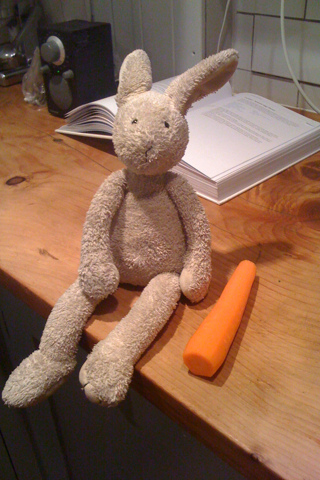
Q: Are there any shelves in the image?
A: No, there are no shelves.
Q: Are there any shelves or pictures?
A: No, there are no shelves or pictures.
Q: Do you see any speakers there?
A: Yes, there is a speaker.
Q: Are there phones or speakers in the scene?
A: Yes, there is a speaker.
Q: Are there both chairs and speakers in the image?
A: No, there is a speaker but no chairs.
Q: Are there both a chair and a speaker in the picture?
A: No, there is a speaker but no chairs.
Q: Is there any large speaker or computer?
A: Yes, there is a large speaker.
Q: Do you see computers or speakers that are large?
A: Yes, the speaker is large.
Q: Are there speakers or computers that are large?
A: Yes, the speaker is large.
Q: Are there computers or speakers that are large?
A: Yes, the speaker is large.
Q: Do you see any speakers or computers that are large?
A: Yes, the speaker is large.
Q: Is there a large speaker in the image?
A: Yes, there is a large speaker.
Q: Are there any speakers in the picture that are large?
A: Yes, there is a speaker that is large.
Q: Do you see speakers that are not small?
A: Yes, there is a large speaker.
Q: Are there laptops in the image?
A: No, there are no laptops.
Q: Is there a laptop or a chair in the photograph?
A: No, there are no laptops or chairs.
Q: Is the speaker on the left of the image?
A: Yes, the speaker is on the left of the image.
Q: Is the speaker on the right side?
A: No, the speaker is on the left of the image.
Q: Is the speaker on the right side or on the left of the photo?
A: The speaker is on the left of the image.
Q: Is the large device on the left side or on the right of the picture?
A: The speaker is on the left of the image.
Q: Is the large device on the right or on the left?
A: The speaker is on the left of the image.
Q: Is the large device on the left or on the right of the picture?
A: The speaker is on the left of the image.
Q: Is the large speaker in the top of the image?
A: Yes, the speaker is in the top of the image.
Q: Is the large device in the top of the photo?
A: Yes, the speaker is in the top of the image.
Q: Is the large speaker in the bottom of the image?
A: No, the speaker is in the top of the image.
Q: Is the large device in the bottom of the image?
A: No, the speaker is in the top of the image.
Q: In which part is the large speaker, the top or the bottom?
A: The speaker is in the top of the image.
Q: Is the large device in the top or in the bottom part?
A: The speaker is in the top of the image.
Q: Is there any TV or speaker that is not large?
A: No, there is a speaker but it is large.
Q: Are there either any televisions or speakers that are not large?
A: No, there is a speaker but it is large.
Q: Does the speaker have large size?
A: Yes, the speaker is large.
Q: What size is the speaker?
A: The speaker is large.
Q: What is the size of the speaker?
A: The speaker is large.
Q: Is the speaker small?
A: No, the speaker is large.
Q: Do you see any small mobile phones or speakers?
A: No, there is a speaker but it is large.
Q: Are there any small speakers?
A: No, there is a speaker but it is large.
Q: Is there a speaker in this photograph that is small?
A: No, there is a speaker but it is large.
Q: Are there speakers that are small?
A: No, there is a speaker but it is large.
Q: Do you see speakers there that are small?
A: No, there is a speaker but it is large.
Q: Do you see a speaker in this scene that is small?
A: No, there is a speaker but it is large.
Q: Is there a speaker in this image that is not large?
A: No, there is a speaker but it is large.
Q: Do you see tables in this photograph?
A: Yes, there is a table.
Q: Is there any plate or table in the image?
A: Yes, there is a table.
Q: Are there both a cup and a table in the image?
A: No, there is a table but no cups.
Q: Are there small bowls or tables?
A: Yes, there is a small table.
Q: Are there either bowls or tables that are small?
A: Yes, the table is small.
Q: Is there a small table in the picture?
A: Yes, there is a small table.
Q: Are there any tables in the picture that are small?
A: Yes, there is a table that is small.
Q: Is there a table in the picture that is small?
A: Yes, there is a table that is small.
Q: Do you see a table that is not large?
A: Yes, there is a small table.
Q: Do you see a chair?
A: No, there are no chairs.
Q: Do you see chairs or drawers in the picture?
A: No, there are no chairs or drawers.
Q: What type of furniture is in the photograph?
A: The furniture is a table.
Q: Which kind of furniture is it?
A: The piece of furniture is a table.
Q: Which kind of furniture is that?
A: This is a table.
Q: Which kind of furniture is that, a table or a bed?
A: This is a table.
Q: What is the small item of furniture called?
A: The piece of furniture is a table.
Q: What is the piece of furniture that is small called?
A: The piece of furniture is a table.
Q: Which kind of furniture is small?
A: The furniture is a table.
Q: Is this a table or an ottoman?
A: This is a table.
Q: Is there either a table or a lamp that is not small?
A: No, there is a table but it is small.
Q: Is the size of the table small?
A: Yes, the table is small.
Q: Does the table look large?
A: No, the table is small.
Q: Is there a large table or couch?
A: No, there is a table but it is small.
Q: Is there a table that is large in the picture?
A: No, there is a table but it is small.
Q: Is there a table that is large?
A: No, there is a table but it is small.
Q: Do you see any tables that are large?
A: No, there is a table but it is small.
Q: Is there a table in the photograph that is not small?
A: No, there is a table but it is small.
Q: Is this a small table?
A: Yes, this is a small table.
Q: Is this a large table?
A: No, this is a small table.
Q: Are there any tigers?
A: No, there are no tigers.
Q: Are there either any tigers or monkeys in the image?
A: No, there are no tigers or monkeys.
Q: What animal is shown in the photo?
A: The animal is a bunny.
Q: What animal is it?
A: The animal is a bunny.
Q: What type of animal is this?
A: This is a bunny.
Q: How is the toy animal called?
A: The animal is a bunny.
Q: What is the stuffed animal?
A: The animal is a bunny.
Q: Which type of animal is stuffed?
A: The animal is a bunny.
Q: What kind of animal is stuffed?
A: The animal is a bunny.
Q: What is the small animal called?
A: The animal is a bunny.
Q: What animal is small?
A: The animal is a bunny.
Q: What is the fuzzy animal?
A: The animal is a bunny.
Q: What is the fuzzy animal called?
A: The animal is a bunny.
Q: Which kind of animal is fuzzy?
A: The animal is a bunny.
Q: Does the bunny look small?
A: Yes, the bunny is small.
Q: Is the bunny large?
A: No, the bunny is small.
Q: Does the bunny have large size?
A: No, the bunny is small.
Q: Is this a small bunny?
A: Yes, this is a small bunny.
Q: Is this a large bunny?
A: No, this is a small bunny.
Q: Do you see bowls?
A: No, there are no bowls.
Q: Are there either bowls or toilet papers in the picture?
A: No, there are no bowls or toilet papers.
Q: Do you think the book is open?
A: Yes, the book is open.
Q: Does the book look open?
A: Yes, the book is open.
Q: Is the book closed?
A: No, the book is open.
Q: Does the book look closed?
A: No, the book is open.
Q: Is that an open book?
A: Yes, that is an open book.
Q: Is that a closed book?
A: No, that is an open book.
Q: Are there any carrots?
A: Yes, there is a carrot.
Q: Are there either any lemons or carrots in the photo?
A: Yes, there is a carrot.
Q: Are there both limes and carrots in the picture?
A: No, there is a carrot but no limes.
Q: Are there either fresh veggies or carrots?
A: Yes, there is a fresh carrot.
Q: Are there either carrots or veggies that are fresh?
A: Yes, the carrot is fresh.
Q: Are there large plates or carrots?
A: Yes, there is a large carrot.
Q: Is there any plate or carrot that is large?
A: Yes, the carrot is large.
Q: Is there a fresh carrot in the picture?
A: Yes, there is a fresh carrot.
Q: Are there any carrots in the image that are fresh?
A: Yes, there is a carrot that is fresh.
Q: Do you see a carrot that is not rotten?
A: Yes, there is a fresh carrot.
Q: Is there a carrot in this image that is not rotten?
A: Yes, there is a fresh carrot.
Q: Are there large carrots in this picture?
A: Yes, there is a large carrot.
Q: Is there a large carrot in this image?
A: Yes, there is a large carrot.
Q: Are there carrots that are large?
A: Yes, there is a carrot that is large.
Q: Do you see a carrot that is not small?
A: Yes, there is a large carrot.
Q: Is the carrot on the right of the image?
A: Yes, the carrot is on the right of the image.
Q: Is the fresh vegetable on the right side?
A: Yes, the carrot is on the right of the image.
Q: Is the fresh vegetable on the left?
A: No, the carrot is on the right of the image.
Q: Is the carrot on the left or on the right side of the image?
A: The carrot is on the right of the image.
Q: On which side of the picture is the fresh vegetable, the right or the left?
A: The carrot is on the right of the image.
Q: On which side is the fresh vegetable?
A: The carrot is on the right of the image.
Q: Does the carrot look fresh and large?
A: Yes, the carrot is fresh and large.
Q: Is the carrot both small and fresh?
A: No, the carrot is fresh but large.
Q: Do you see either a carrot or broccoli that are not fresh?
A: No, there is a carrot but it is fresh.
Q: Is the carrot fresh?
A: Yes, the carrot is fresh.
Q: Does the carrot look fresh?
A: Yes, the carrot is fresh.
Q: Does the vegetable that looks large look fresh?
A: Yes, the carrot is fresh.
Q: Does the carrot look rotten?
A: No, the carrot is fresh.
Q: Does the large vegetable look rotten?
A: No, the carrot is fresh.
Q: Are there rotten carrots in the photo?
A: No, there is a carrot but it is fresh.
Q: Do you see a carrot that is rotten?
A: No, there is a carrot but it is fresh.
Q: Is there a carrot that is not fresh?
A: No, there is a carrot but it is fresh.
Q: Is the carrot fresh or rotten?
A: The carrot is fresh.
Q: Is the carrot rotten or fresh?
A: The carrot is fresh.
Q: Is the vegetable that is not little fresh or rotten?
A: The carrot is fresh.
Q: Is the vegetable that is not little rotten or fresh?
A: The carrot is fresh.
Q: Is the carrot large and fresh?
A: Yes, the carrot is large and fresh.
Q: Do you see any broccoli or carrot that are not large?
A: No, there is a carrot but it is large.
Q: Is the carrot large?
A: Yes, the carrot is large.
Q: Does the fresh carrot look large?
A: Yes, the carrot is large.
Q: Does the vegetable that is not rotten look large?
A: Yes, the carrot is large.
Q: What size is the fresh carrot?
A: The carrot is large.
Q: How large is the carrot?
A: The carrot is large.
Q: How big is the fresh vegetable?
A: The carrot is large.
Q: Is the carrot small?
A: No, the carrot is large.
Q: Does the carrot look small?
A: No, the carrot is large.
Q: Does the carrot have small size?
A: No, the carrot is large.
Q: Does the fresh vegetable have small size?
A: No, the carrot is large.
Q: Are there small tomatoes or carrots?
A: No, there is a carrot but it is large.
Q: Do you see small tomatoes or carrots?
A: No, there is a carrot but it is large.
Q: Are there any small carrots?
A: No, there is a carrot but it is large.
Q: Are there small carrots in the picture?
A: No, there is a carrot but it is large.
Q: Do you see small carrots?
A: No, there is a carrot but it is large.